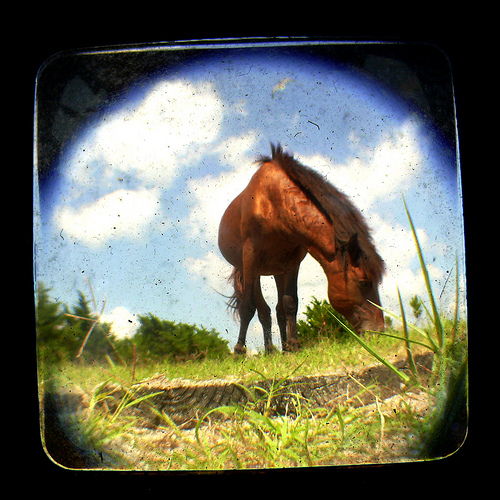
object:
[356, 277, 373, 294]
eye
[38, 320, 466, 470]
ground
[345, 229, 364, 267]
ear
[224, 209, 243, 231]
hair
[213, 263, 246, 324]
tail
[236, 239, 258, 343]
legs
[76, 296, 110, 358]
twig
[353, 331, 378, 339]
mouth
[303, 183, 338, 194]
hair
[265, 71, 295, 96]
bird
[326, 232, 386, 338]
head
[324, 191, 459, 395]
grass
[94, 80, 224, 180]
clouds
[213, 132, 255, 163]
clouds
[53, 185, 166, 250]
clouds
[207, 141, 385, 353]
horse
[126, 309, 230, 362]
green bush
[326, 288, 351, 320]
jaw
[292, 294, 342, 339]
trees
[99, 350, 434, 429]
wooden edging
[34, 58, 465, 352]
sky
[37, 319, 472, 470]
field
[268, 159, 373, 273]
neck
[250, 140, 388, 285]
mane